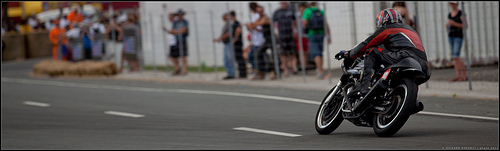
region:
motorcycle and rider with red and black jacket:
[310, 8, 440, 136]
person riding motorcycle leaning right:
[308, 4, 434, 139]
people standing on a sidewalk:
[42, 2, 329, 82]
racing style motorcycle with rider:
[307, 6, 435, 136]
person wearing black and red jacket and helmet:
[308, 4, 434, 139]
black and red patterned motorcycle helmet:
[373, 7, 405, 30]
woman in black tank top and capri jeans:
[438, 1, 475, 83]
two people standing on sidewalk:
[163, 5, 194, 79]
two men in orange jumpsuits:
[46, 7, 87, 69]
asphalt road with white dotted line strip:
[10, 80, 302, 149]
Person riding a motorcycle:
[312, 6, 432, 135]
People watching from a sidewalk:
[45, 2, 474, 84]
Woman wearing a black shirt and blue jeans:
[442, 0, 470, 85]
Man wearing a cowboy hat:
[172, 4, 192, 75]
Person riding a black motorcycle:
[315, 5, 431, 140]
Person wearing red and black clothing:
[335, 8, 432, 94]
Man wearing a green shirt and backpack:
[300, 0, 333, 79]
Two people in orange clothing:
[51, 5, 81, 65]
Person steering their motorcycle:
[315, 7, 432, 136]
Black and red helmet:
[375, 5, 403, 30]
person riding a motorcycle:
[319, 8, 439, 131]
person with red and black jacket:
[348, 17, 423, 63]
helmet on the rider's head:
[362, 11, 400, 26]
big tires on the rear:
[369, 92, 415, 139]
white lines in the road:
[3, 80, 288, 140]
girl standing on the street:
[433, 1, 464, 93]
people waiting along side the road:
[140, 2, 323, 84]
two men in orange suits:
[41, 1, 78, 61]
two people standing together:
[161, 0, 195, 93]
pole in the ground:
[450, 0, 477, 106]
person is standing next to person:
[161, 9, 180, 73]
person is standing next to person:
[212, 10, 238, 79]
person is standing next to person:
[224, 7, 248, 79]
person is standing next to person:
[249, 3, 264, 78]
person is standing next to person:
[248, 5, 279, 80]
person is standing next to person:
[274, 1, 302, 76]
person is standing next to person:
[298, 0, 335, 81]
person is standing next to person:
[45, 18, 66, 60]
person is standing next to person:
[66, 22, 86, 64]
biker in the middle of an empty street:
[315, 10, 430, 132]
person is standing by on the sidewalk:
[172, 8, 192, 78]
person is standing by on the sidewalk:
[445, 2, 467, 81]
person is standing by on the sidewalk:
[215, 8, 236, 79]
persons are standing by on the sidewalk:
[246, 0, 271, 77]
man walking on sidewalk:
[301, 2, 329, 75]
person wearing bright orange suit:
[49, 20, 68, 57]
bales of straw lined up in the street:
[33, 54, 115, 76]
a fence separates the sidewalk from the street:
[137, 6, 337, 81]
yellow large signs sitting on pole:
[7, 0, 42, 61]